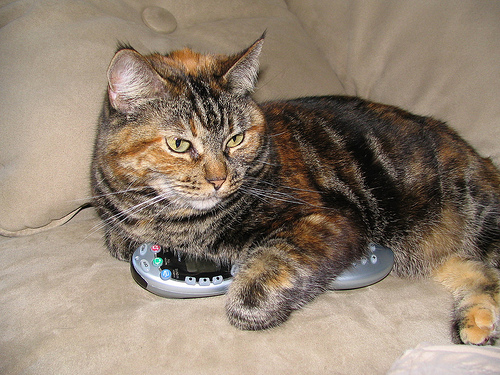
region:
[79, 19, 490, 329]
This is a cat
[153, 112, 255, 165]
Eyes of a cat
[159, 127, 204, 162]
Eye of a cat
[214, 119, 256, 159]
Eye of a cat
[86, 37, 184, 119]
Ear of a cat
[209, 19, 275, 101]
Ear of a cat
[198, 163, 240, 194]
Nose of a cat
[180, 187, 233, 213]
Mouth of a cat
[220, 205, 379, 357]
Leg of a cat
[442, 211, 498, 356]
Leg of a cat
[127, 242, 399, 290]
Remote control under cat.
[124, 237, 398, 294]
Gray and black remote control.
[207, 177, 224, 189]
Pink cat nose.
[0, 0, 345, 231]
Tan couch pillow.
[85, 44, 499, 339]
Brown and black cat on sofa.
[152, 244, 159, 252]
Red button on remote control.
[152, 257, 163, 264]
Green round button on remote.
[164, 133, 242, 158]
Green cat eyes.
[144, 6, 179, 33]
Button in middle of pillow.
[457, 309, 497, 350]
Cat's paws on couch.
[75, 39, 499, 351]
brown black and gold calico cat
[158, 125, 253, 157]
yellow eyes on calico cat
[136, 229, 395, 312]
silver remote control held by cat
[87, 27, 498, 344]
cat holding and sitting on remote control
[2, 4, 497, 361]
creamy beige fabric couch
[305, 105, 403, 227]
black stripes on calico cat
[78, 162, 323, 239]
white whiskers on calico cat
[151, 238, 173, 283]
red, blue and green remote control buttons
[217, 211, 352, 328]
paw wrapped around remote control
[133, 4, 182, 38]
button in tufted cushion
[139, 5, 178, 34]
cloth covered decorative couch button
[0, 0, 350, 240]
tan cloth couch arm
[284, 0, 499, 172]
tan cloth back cushion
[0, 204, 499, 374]
tan couch seat cushion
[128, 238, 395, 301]
silver television remote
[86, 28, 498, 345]
orange, black, and cream calico cat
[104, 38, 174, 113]
cats' pointed and tufted ear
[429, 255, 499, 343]
cats' back leg and paw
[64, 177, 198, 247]
cats white whiskers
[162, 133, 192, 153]
cats green-gold colored eye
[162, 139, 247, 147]
cat has green eyes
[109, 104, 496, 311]
cat sitting on the remote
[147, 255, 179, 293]
remote has two blue buttons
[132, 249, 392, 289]
remote is gray with buttons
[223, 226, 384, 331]
cats paw is on remote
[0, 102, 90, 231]
pillow has white slipcover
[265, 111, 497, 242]
cat has black and grey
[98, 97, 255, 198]
cat is looking to his left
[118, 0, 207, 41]
button on the pillow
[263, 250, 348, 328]
bottom paw is gray